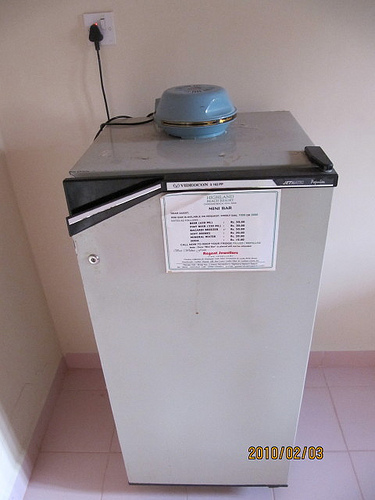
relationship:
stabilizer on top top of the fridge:
[150, 79, 235, 142] [71, 110, 318, 171]